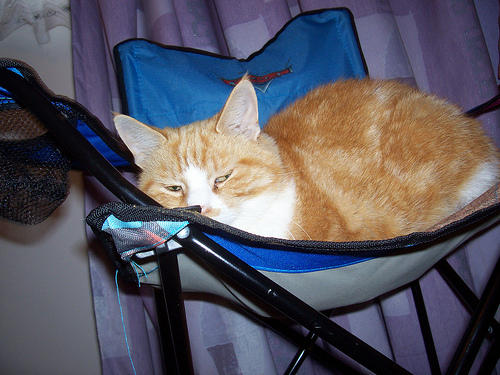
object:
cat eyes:
[162, 181, 185, 195]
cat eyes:
[212, 170, 235, 187]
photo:
[6, 3, 484, 373]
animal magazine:
[85, 6, 500, 318]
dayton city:
[2, 3, 492, 361]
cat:
[113, 80, 499, 242]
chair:
[0, 6, 499, 373]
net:
[2, 94, 77, 225]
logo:
[222, 64, 296, 94]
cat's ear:
[109, 111, 168, 168]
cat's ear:
[213, 72, 261, 138]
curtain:
[69, 0, 500, 375]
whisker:
[226, 190, 288, 223]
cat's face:
[143, 128, 268, 217]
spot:
[178, 148, 212, 213]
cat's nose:
[190, 205, 218, 215]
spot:
[249, 188, 291, 221]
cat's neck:
[262, 109, 298, 239]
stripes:
[167, 117, 207, 177]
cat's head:
[112, 80, 297, 238]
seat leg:
[146, 249, 201, 374]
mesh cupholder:
[0, 56, 137, 223]